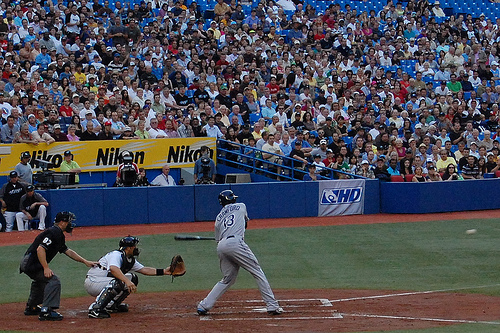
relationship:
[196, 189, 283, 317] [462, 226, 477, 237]
baseball player ready to hit ball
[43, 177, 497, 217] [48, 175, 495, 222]
padding on fence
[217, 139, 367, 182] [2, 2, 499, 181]
railing around spectators